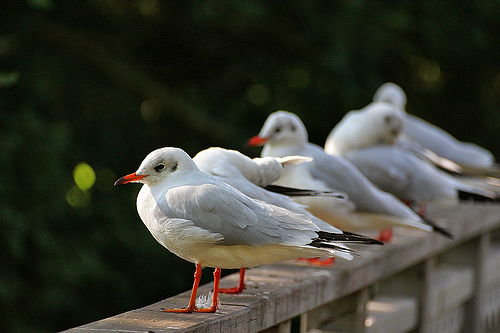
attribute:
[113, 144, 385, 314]
bird — black , facing left, sunning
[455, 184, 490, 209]
tail — black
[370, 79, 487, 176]
bird — white, gray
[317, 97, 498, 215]
bird — white, gray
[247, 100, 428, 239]
bird — white, gray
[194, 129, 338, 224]
bird — white, gray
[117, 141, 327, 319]
bird — white, gray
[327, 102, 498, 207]
seagull — grooming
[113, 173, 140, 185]
beak — orange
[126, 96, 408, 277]
seagull — resting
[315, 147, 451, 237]
wing — gray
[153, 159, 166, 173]
eye — black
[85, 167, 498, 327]
ledge — wood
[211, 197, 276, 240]
wing — gray 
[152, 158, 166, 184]
eye — dark 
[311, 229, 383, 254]
tail feathers — black, few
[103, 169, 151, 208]
beak — black, orange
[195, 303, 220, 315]
foot — bird's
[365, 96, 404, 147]
head — turned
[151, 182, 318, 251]
wing — gray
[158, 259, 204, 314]
leg — orange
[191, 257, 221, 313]
leg — orange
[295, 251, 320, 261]
leg — orange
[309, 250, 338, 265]
leg — orange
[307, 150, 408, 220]
wing — gray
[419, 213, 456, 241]
tail feather — black